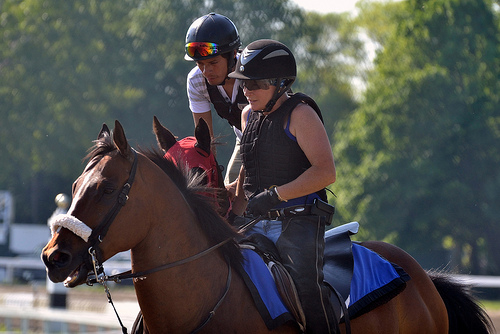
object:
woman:
[225, 39, 342, 334]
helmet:
[228, 39, 298, 81]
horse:
[37, 119, 494, 334]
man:
[182, 8, 250, 185]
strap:
[112, 215, 265, 279]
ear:
[277, 85, 286, 94]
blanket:
[233, 241, 412, 331]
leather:
[192, 261, 233, 331]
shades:
[244, 83, 269, 90]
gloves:
[247, 185, 288, 217]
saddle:
[238, 247, 268, 272]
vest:
[239, 91, 324, 200]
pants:
[232, 210, 339, 333]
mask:
[162, 136, 221, 212]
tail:
[425, 271, 497, 334]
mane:
[138, 147, 247, 268]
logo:
[241, 46, 262, 65]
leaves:
[10, 1, 107, 56]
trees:
[337, 0, 500, 256]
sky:
[296, 0, 351, 17]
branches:
[325, 11, 357, 38]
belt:
[266, 204, 312, 218]